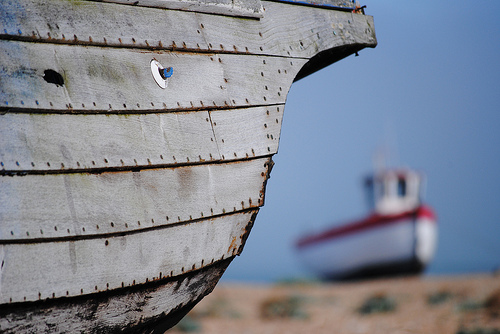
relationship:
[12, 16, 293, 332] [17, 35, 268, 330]
boat has wood panels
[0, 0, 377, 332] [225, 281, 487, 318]
boat are on shore